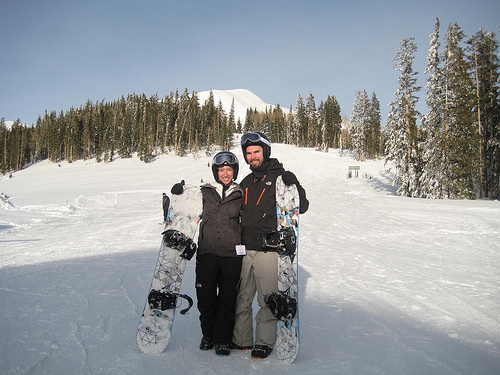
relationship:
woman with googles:
[197, 148, 241, 357] [210, 147, 240, 171]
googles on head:
[210, 147, 240, 171] [208, 148, 244, 188]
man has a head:
[238, 125, 306, 366] [227, 120, 275, 168]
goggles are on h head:
[235, 130, 265, 143] [227, 120, 275, 168]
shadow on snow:
[13, 256, 123, 346] [2, 149, 498, 369]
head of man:
[240, 131, 270, 169] [222, 129, 310, 361]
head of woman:
[209, 150, 238, 184] [170, 148, 245, 359]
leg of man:
[248, 252, 278, 358] [222, 129, 310, 361]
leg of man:
[237, 250, 254, 350] [222, 129, 310, 361]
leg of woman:
[214, 256, 239, 354] [170, 148, 245, 359]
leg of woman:
[193, 252, 217, 351] [170, 148, 245, 359]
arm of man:
[276, 170, 309, 213] [222, 129, 310, 361]